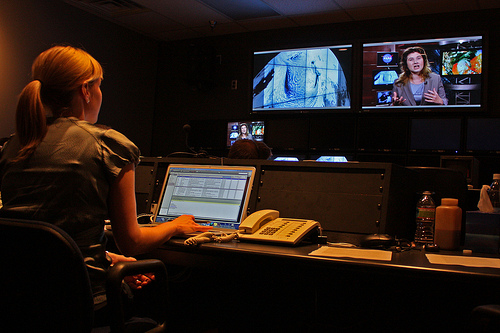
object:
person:
[1, 47, 213, 326]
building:
[0, 2, 499, 332]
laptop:
[138, 163, 257, 230]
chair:
[2, 218, 164, 331]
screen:
[251, 48, 349, 109]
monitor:
[159, 167, 248, 223]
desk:
[97, 230, 499, 285]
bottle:
[414, 189, 440, 251]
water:
[414, 190, 433, 249]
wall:
[0, 0, 192, 135]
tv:
[361, 35, 482, 110]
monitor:
[228, 121, 264, 141]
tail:
[14, 80, 46, 146]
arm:
[106, 258, 170, 332]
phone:
[182, 209, 323, 248]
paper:
[307, 245, 392, 261]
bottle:
[433, 197, 464, 251]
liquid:
[433, 229, 459, 250]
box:
[465, 232, 500, 257]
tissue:
[476, 183, 496, 214]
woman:
[390, 46, 447, 105]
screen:
[363, 37, 481, 108]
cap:
[463, 249, 473, 255]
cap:
[440, 196, 458, 206]